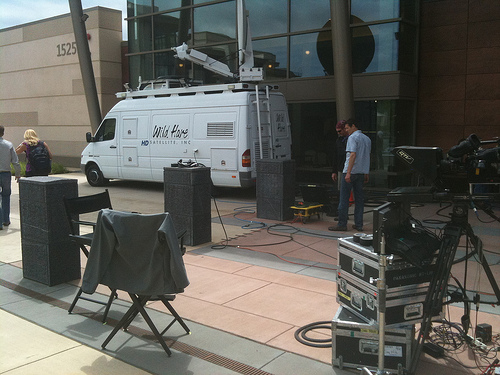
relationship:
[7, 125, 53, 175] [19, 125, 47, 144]
woman has blonde hair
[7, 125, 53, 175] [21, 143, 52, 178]
woman wears bookbag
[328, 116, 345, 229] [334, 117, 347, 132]
man wears bandana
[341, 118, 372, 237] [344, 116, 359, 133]
man has black hair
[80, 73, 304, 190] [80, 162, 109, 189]
truck has front wheel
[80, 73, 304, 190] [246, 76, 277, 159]
truck has ladder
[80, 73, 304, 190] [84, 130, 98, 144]
truck has mirror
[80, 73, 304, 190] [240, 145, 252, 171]
truck has brake light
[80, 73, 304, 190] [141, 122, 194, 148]
truck has words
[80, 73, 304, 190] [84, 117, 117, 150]
truck has window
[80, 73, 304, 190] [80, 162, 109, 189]
truck has tire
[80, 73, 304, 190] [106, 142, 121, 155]
truck has door handle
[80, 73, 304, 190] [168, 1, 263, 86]
truck has antennae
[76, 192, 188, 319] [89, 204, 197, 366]
coat on chair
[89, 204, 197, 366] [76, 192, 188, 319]
chair has coat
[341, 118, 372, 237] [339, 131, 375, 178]
man wears blue shirt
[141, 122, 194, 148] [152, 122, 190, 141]
words say wild hare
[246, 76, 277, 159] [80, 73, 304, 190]
ladder fastened to truck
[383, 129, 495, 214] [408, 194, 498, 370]
camera on tripod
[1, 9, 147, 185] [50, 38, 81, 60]
building has number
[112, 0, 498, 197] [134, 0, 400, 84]
building has glass windows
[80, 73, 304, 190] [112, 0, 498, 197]
truck in front of building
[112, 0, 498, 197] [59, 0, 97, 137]
building has pole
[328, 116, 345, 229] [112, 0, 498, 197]
man in front of building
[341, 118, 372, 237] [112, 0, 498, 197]
man in front of building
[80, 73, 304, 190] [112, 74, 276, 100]
truck has roof rack